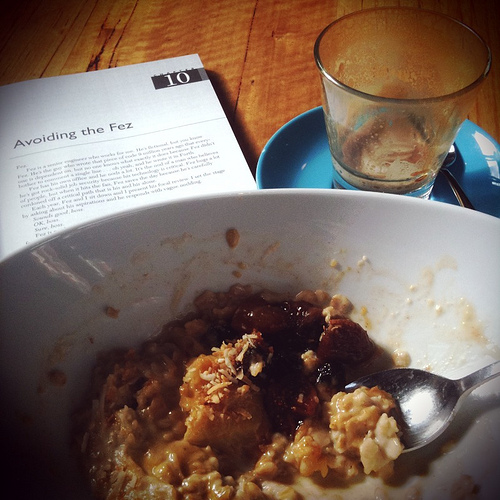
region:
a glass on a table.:
[300, 27, 498, 189]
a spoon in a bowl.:
[284, 340, 498, 457]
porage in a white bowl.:
[42, 287, 420, 496]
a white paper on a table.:
[0, 35, 262, 282]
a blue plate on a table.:
[249, 84, 498, 219]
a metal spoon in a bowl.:
[341, 341, 489, 473]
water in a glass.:
[333, 92, 440, 182]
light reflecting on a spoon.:
[390, 349, 448, 449]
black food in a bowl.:
[242, 286, 369, 383]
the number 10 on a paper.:
[143, 35, 223, 103]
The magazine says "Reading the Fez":
[11, 128, 119, 151]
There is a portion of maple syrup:
[276, 305, 326, 396]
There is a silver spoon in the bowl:
[413, 354, 455, 432]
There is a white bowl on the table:
[408, 288, 462, 350]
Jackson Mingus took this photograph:
[100, 136, 463, 469]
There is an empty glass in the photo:
[328, 17, 462, 152]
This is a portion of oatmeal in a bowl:
[169, 313, 338, 488]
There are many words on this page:
[45, 171, 115, 203]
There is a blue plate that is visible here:
[298, 123, 315, 159]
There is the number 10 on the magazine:
[143, 51, 209, 98]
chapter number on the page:
[156, 68, 207, 86]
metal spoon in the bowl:
[351, 358, 495, 449]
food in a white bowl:
[76, 287, 400, 496]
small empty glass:
[311, 8, 488, 198]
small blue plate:
[258, 103, 499, 198]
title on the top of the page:
[16, 124, 134, 148]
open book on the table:
[1, 52, 255, 259]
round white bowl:
[2, 191, 499, 490]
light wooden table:
[4, 3, 499, 146]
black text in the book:
[1, 134, 242, 231]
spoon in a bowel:
[232, 184, 497, 498]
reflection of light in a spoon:
[370, 352, 477, 461]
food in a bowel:
[120, 199, 477, 498]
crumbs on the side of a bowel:
[293, 253, 460, 325]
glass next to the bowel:
[296, 8, 485, 204]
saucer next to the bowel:
[236, 110, 498, 234]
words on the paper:
[6, 112, 143, 157]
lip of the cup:
[290, 57, 487, 113]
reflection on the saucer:
[459, 127, 496, 168]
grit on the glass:
[298, 48, 450, 108]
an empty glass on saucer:
[306, 51, 498, 211]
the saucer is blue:
[246, 84, 369, 199]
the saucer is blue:
[283, 95, 486, 201]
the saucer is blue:
[388, 68, 496, 215]